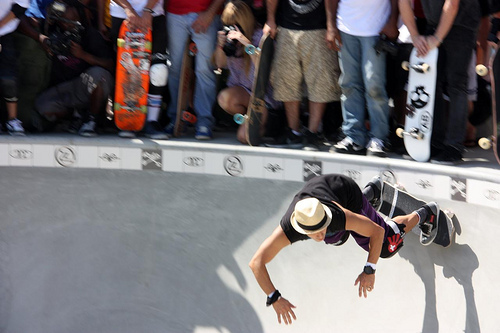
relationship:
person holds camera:
[210, 2, 265, 143] [218, 18, 243, 58]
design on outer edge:
[136, 145, 169, 176] [1, 134, 495, 214]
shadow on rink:
[387, 231, 485, 332] [4, 129, 499, 331]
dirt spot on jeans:
[368, 84, 394, 113] [329, 26, 393, 146]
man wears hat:
[247, 178, 443, 326] [285, 196, 336, 242]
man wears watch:
[247, 178, 443, 326] [362, 263, 375, 278]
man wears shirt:
[247, 178, 443, 326] [276, 170, 363, 246]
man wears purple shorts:
[247, 178, 443, 326] [324, 193, 389, 254]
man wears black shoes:
[247, 178, 443, 326] [365, 177, 441, 250]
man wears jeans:
[320, 0, 402, 160] [329, 26, 393, 146]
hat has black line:
[285, 196, 336, 242] [294, 212, 331, 232]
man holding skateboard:
[391, 2, 478, 173] [400, 30, 446, 165]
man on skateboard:
[247, 178, 443, 326] [364, 177, 461, 258]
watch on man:
[362, 263, 375, 278] [247, 178, 443, 326]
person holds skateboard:
[103, 1, 173, 144] [110, 10, 153, 133]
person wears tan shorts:
[261, 0, 345, 148] [255, 21, 342, 112]